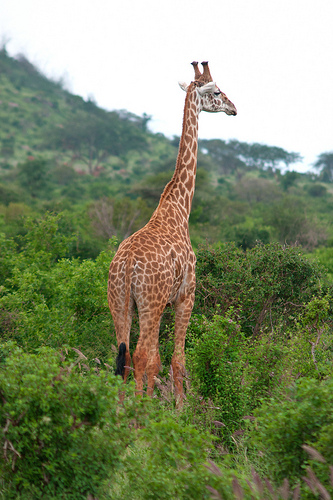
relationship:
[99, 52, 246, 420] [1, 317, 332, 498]
giraffe in weeds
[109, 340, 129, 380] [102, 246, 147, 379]
hair on tail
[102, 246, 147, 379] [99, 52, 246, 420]
tail of giraffe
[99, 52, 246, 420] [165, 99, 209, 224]
giraffe with neck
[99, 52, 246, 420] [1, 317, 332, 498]
giraffe on weeds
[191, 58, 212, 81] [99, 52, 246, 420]
horns on giraffe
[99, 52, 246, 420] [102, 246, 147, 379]
giraffe has tail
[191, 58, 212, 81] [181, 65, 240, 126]
horns on head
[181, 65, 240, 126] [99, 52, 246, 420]
head on giraffe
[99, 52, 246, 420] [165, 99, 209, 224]
giraffe has neck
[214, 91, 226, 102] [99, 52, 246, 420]
eye on giraffe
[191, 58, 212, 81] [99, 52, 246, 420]
horns of giraffe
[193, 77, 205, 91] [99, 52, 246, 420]
ears of giraffe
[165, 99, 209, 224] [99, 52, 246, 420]
neck of giraffe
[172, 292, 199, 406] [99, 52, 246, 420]
leg of giraffe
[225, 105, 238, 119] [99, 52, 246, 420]
mouth of giraffe